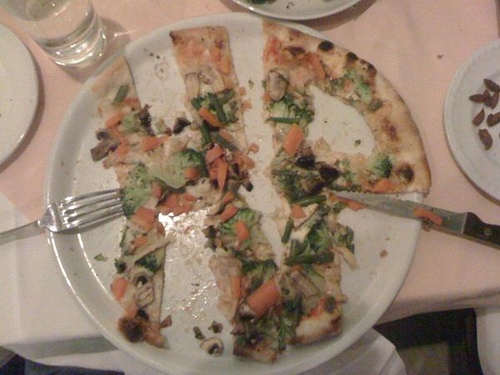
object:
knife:
[336, 187, 500, 249]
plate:
[41, 10, 437, 374]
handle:
[461, 209, 499, 250]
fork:
[0, 188, 128, 251]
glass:
[3, 1, 113, 73]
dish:
[92, 18, 431, 364]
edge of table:
[1, 291, 464, 375]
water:
[15, 4, 111, 72]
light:
[52, 33, 107, 69]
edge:
[116, 321, 394, 374]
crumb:
[201, 338, 227, 359]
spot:
[318, 38, 336, 53]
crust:
[261, 21, 393, 94]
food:
[410, 206, 447, 228]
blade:
[331, 188, 467, 241]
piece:
[231, 316, 285, 364]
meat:
[240, 319, 271, 352]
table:
[338, 13, 499, 294]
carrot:
[249, 281, 283, 312]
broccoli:
[278, 158, 341, 200]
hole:
[301, 83, 378, 160]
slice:
[255, 22, 431, 205]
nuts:
[471, 69, 499, 154]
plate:
[443, 36, 499, 200]